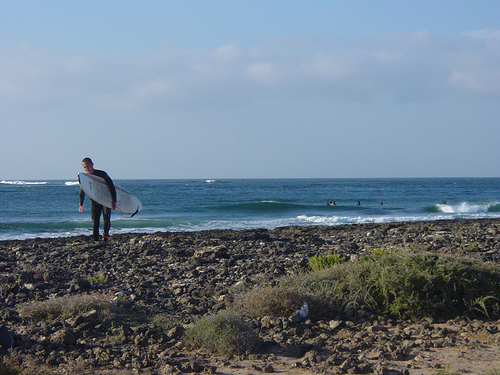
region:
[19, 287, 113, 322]
a patch of green and brown vegetation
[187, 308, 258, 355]
a patch of green and brown vegetation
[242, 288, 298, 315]
a patch of green and brown vegetation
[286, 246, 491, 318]
a patch of green and brown vegetation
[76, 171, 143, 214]
a white and red long surfboard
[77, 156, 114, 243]
a man walking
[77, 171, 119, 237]
a black long sleeved wetsuit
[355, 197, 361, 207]
a person in the ocean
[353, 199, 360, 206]
a person in the ocean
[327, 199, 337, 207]
a person in the ocean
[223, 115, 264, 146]
this is the sky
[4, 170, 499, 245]
this is the ocean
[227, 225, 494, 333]
this is the grass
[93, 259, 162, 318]
these are the rocks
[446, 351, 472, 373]
this is the sand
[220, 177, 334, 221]
this is a wave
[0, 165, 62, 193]
this is a wave breaking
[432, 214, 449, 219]
this is ocean foam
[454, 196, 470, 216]
this is white ocean spray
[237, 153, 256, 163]
this is the color blue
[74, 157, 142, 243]
Man carrying a surfboard.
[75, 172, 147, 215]
White surfboard with strip.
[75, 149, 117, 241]
Man in black wetsuit.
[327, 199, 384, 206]
people at a distant in ocean.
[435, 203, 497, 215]
Wave breaking against shore.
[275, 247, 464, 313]
Patch of grass on beach.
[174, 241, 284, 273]
Rocky beach shore.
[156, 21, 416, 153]
Blue sky with light clouds.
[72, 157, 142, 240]
Man on beach with surfboard.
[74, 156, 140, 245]
Man leaving beach with surfboard.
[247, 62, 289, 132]
part of a cloud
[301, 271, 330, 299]
part of a plant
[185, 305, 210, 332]
part of a plant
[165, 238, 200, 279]
part of a ground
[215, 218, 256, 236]
edge of a shore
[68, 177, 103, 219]
edge of a board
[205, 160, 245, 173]
part of a cloud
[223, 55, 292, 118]
part of a cloud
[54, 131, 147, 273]
surfer on the beach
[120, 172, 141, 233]
white surfboard in man's hand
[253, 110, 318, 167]
blue sky above water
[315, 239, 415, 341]
green grass on beach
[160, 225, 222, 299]
rocks on the ground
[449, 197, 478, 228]
white water in ocean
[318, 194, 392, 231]
people in the water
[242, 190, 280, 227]
wave forming in the ocean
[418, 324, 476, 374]
brown dirt on floor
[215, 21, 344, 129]
white clouds in sky